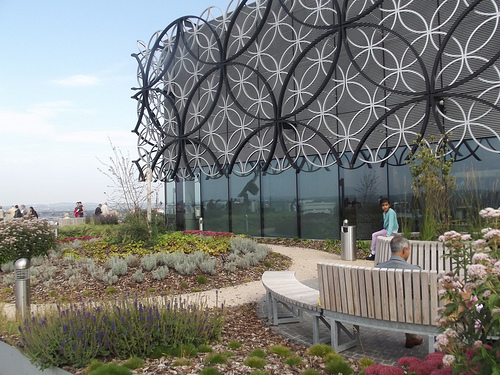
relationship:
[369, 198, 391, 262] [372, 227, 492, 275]
child sitting on a bench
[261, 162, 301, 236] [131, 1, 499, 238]
window on side of building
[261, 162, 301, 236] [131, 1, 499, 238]
window on building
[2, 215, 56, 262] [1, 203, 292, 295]
flowers are in garden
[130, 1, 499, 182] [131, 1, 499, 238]
design on side of building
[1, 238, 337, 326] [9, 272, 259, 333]
path in space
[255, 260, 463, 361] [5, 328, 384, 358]
seat in space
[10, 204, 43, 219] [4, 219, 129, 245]
people near space